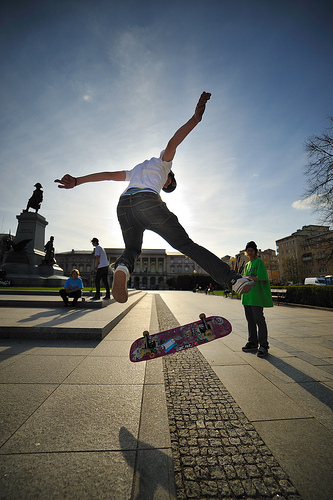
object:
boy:
[237, 236, 276, 358]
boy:
[51, 87, 255, 306]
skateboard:
[129, 313, 232, 364]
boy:
[58, 269, 84, 304]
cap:
[239, 240, 259, 254]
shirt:
[234, 256, 285, 314]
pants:
[238, 306, 270, 351]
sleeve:
[254, 260, 276, 283]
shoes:
[256, 347, 268, 357]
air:
[104, 306, 294, 469]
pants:
[106, 182, 239, 289]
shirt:
[116, 145, 178, 198]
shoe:
[110, 264, 135, 308]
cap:
[164, 170, 177, 193]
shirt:
[60, 277, 88, 293]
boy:
[89, 235, 111, 301]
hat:
[90, 237, 99, 242]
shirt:
[91, 244, 116, 273]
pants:
[94, 265, 110, 304]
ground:
[2, 332, 333, 500]